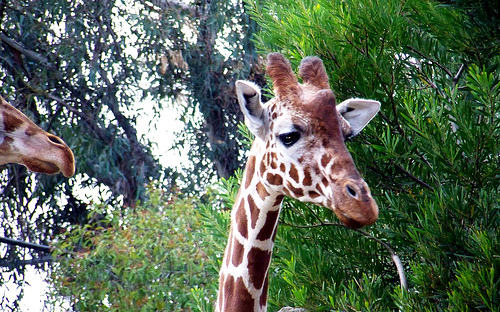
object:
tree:
[334, 25, 456, 146]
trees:
[48, 0, 237, 153]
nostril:
[46, 133, 63, 146]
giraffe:
[0, 96, 77, 178]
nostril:
[339, 180, 362, 202]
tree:
[228, 3, 496, 310]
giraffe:
[212, 50, 384, 312]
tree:
[41, 25, 213, 253]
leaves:
[40, 102, 75, 139]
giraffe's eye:
[276, 130, 304, 151]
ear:
[337, 96, 382, 140]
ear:
[232, 78, 265, 126]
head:
[231, 51, 386, 231]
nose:
[339, 177, 381, 219]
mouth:
[327, 205, 378, 228]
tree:
[403, 110, 463, 210]